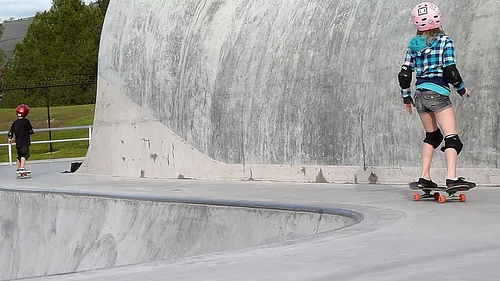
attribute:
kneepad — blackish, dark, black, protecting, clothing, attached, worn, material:
[426, 124, 462, 157]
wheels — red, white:
[412, 190, 460, 206]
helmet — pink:
[408, 2, 444, 34]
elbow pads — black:
[396, 67, 461, 88]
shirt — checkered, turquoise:
[396, 33, 464, 97]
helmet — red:
[14, 103, 31, 117]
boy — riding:
[6, 101, 38, 181]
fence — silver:
[0, 83, 100, 158]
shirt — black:
[10, 118, 38, 145]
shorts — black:
[11, 140, 32, 161]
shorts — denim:
[414, 90, 450, 114]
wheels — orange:
[15, 171, 34, 183]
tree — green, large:
[17, 0, 94, 107]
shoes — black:
[416, 172, 475, 188]